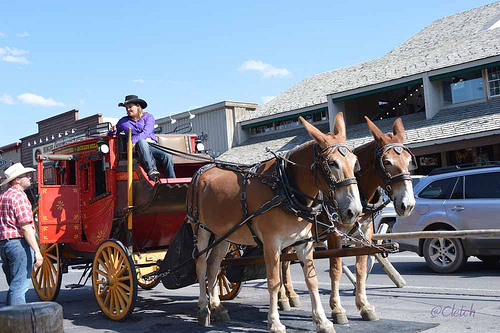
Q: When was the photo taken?
A: Daytime.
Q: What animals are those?
A: Horses.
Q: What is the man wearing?
A: Jeans.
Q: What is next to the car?
A: A building.